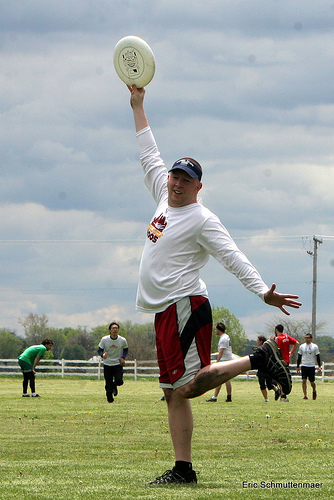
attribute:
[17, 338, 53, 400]
man — hunced over, tired, bending over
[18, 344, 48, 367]
shirt — green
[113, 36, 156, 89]
frisbee — held, white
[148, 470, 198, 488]
shoe — black, muddy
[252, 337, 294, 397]
shoe — black, muddy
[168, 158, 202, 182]
visor — blue, black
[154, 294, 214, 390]
shorts — red, black, white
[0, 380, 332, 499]
field — mowed, grassy, green, large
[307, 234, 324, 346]
pole — wooden, tall, electrical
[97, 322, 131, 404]
man — running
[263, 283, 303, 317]
hand — spread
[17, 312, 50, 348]
tree — lined up, in background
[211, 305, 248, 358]
tree — lined up, in background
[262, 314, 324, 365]
tree — lined up, in background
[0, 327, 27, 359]
tree — lined up, in background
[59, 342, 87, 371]
tree — lined up, in background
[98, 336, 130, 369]
shirt — white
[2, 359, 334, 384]
fence — in background, white, wooden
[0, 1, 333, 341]
sky — cloudy, blue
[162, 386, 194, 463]
leg — muddy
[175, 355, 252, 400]
leg — muddy, bent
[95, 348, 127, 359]
shirt — long sleeved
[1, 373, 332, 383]
grass — tall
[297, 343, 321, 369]
shirt — white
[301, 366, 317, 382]
shorts — black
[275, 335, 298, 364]
shirt — red